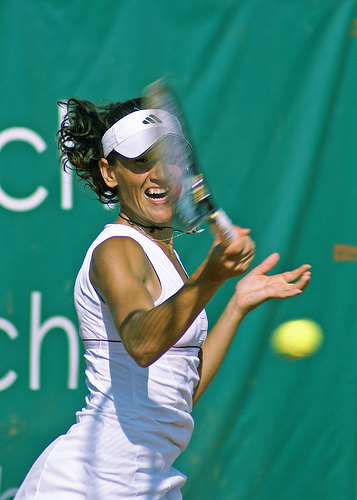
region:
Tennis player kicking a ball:
[0, 54, 323, 498]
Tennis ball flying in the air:
[265, 312, 333, 370]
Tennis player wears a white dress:
[4, 79, 329, 498]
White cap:
[89, 102, 203, 178]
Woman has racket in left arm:
[2, 62, 337, 498]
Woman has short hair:
[0, 66, 330, 497]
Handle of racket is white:
[205, 201, 258, 270]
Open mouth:
[137, 182, 174, 203]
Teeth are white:
[146, 188, 168, 200]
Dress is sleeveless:
[9, 210, 213, 497]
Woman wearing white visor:
[80, 107, 233, 177]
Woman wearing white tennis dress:
[68, 318, 197, 486]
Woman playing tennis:
[51, 165, 277, 490]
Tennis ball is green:
[270, 300, 318, 388]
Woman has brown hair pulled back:
[60, 103, 173, 169]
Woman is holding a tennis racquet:
[123, 78, 271, 252]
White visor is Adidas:
[95, 107, 254, 186]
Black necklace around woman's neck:
[115, 204, 218, 251]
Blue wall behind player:
[21, 38, 327, 370]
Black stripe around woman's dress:
[83, 333, 208, 371]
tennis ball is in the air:
[257, 305, 336, 370]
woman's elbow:
[119, 306, 184, 372]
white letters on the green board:
[0, 287, 97, 404]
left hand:
[229, 245, 327, 310]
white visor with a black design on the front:
[87, 107, 205, 156]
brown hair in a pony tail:
[38, 75, 162, 204]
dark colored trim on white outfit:
[66, 329, 223, 374]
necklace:
[113, 202, 218, 244]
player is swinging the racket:
[119, 72, 275, 278]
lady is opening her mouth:
[140, 179, 186, 212]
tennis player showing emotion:
[44, 84, 318, 478]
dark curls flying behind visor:
[30, 79, 208, 233]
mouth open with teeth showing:
[127, 176, 183, 200]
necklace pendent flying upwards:
[103, 199, 208, 244]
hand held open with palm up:
[225, 240, 327, 325]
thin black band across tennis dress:
[55, 322, 213, 361]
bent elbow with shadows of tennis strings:
[75, 217, 249, 363]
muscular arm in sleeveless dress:
[80, 230, 177, 329]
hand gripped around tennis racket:
[197, 193, 253, 276]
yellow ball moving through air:
[221, 276, 342, 379]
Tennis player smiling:
[4, 72, 316, 498]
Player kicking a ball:
[6, 59, 355, 498]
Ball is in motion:
[262, 306, 332, 371]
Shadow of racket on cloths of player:
[57, 373, 186, 496]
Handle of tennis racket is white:
[207, 202, 253, 254]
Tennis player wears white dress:
[5, 83, 325, 494]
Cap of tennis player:
[84, 99, 193, 173]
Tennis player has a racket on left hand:
[3, 55, 333, 497]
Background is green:
[3, 8, 355, 497]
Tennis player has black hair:
[8, 69, 355, 494]